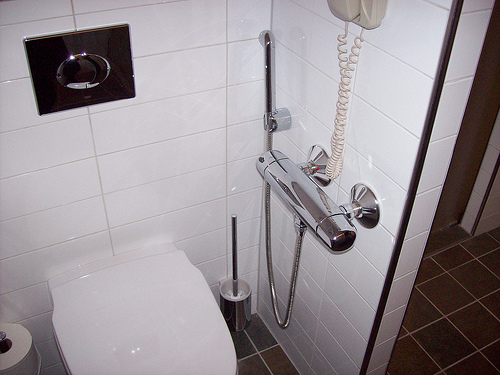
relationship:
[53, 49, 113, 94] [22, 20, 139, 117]
button on plate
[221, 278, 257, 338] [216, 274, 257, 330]
brush in cup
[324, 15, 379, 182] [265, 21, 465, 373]
phone on wall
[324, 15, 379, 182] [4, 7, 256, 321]
phone on wall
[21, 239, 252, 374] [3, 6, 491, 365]
toilet in bathroom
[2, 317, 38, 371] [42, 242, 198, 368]
roll next toilet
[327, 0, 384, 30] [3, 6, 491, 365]
phone in bathroom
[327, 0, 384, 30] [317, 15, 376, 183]
phone has cord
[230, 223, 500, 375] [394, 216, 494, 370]
tile on floor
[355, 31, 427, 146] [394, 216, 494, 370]
tile on floor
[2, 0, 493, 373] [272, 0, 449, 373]
white tiles on wall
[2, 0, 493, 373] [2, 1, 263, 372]
white tiles on wall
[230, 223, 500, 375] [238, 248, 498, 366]
tile on floor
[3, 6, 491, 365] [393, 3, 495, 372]
bathroom has door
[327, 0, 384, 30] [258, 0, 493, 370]
phone on wall